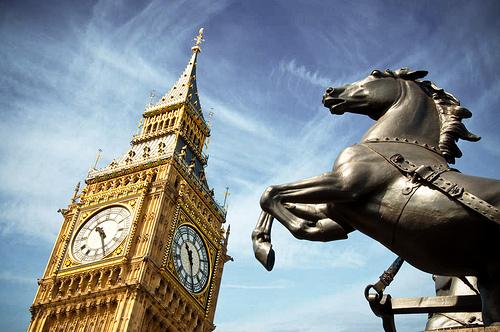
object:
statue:
[247, 62, 500, 332]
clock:
[67, 203, 133, 265]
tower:
[23, 22, 239, 332]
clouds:
[88, 58, 112, 69]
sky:
[0, 0, 500, 332]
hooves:
[254, 242, 277, 272]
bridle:
[319, 64, 448, 157]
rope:
[373, 254, 406, 294]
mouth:
[320, 97, 348, 115]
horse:
[249, 64, 500, 331]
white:
[101, 206, 131, 221]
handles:
[95, 226, 107, 238]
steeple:
[143, 20, 211, 129]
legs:
[255, 171, 351, 244]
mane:
[419, 79, 485, 164]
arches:
[83, 269, 98, 296]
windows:
[143, 263, 158, 289]